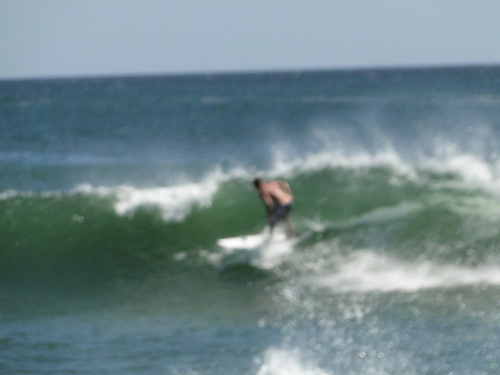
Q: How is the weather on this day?
A: It is clear.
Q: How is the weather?
A: It is clear.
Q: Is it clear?
A: Yes, it is clear.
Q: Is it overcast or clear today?
A: It is clear.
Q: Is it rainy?
A: No, it is clear.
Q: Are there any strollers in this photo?
A: No, there are no strollers.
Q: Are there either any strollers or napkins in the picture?
A: No, there are no strollers or napkins.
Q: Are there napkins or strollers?
A: No, there are no strollers or napkins.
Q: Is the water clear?
A: Yes, the water is clear.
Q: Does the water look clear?
A: Yes, the water is clear.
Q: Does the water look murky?
A: No, the water is clear.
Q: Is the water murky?
A: No, the water is clear.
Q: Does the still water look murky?
A: No, the water is clear.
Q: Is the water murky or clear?
A: The water is clear.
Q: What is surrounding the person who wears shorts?
A: The water is surrounding the surfer.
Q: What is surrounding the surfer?
A: The water is surrounding the surfer.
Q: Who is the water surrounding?
A: The water is surrounding the surfer.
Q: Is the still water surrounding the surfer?
A: Yes, the water is surrounding the surfer.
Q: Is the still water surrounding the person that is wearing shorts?
A: Yes, the water is surrounding the surfer.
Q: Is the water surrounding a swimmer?
A: No, the water is surrounding the surfer.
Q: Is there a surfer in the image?
A: Yes, there is a surfer.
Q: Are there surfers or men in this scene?
A: Yes, there is a surfer.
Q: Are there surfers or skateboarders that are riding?
A: Yes, the surfer is riding.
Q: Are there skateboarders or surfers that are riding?
A: Yes, the surfer is riding.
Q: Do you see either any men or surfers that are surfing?
A: Yes, the surfer is surfing.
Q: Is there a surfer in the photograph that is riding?
A: Yes, there is a surfer that is riding.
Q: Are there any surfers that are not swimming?
A: Yes, there is a surfer that is riding.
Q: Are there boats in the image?
A: No, there are no boats.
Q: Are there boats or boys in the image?
A: No, there are no boats or boys.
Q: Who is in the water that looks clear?
A: The surfer is in the water.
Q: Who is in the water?
A: The surfer is in the water.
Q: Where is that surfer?
A: The surfer is in the water.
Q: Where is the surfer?
A: The surfer is in the water.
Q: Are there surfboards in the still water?
A: No, there is a surfer in the water.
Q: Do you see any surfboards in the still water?
A: No, there is a surfer in the water.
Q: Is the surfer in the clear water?
A: Yes, the surfer is in the water.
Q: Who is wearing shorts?
A: The surfer is wearing shorts.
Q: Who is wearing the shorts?
A: The surfer is wearing shorts.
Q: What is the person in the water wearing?
A: The surfer is wearing shorts.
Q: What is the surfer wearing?
A: The surfer is wearing shorts.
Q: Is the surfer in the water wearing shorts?
A: Yes, the surfer is wearing shorts.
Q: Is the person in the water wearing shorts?
A: Yes, the surfer is wearing shorts.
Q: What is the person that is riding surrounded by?
A: The surfer is surrounded by the water.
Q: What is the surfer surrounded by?
A: The surfer is surrounded by the water.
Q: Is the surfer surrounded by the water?
A: Yes, the surfer is surrounded by the water.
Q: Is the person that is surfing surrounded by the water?
A: Yes, the surfer is surrounded by the water.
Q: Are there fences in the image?
A: No, there are no fences.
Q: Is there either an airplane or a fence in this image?
A: No, there are no fences or airplanes.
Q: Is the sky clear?
A: Yes, the sky is clear.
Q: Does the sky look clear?
A: Yes, the sky is clear.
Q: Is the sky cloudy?
A: No, the sky is clear.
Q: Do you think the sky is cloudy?
A: No, the sky is clear.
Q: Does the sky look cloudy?
A: No, the sky is clear.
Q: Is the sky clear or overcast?
A: The sky is clear.